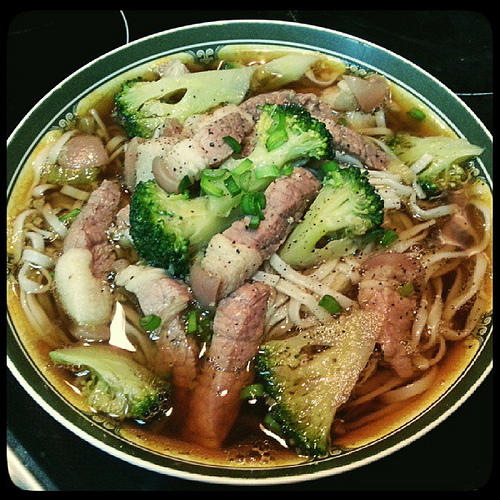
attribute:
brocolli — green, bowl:
[135, 170, 231, 254]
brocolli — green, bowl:
[107, 70, 272, 119]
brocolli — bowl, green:
[136, 172, 239, 262]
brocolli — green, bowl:
[49, 340, 170, 432]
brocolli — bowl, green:
[265, 149, 386, 242]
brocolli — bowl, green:
[248, 101, 386, 250]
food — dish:
[139, 150, 400, 369]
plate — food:
[393, 413, 416, 451]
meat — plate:
[196, 373, 239, 430]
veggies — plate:
[278, 323, 364, 411]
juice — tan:
[204, 435, 276, 456]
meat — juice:
[214, 312, 251, 358]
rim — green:
[434, 385, 463, 419]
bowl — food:
[22, 28, 484, 472]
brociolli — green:
[128, 178, 206, 261]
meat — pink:
[190, 299, 262, 426]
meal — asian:
[13, 49, 484, 449]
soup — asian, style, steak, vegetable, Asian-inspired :
[10, 50, 475, 450]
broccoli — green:
[51, 65, 476, 434]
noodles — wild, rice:
[11, 46, 462, 448]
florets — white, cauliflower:
[54, 245, 189, 333]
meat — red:
[184, 280, 269, 443]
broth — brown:
[240, 416, 285, 444]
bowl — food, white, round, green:
[4, 13, 473, 483]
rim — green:
[300, 370, 485, 479]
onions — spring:
[224, 177, 263, 228]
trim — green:
[17, 390, 471, 480]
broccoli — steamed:
[141, 104, 375, 294]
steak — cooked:
[186, 290, 280, 450]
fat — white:
[199, 230, 259, 293]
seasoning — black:
[102, 119, 371, 351]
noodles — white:
[8, 141, 477, 415]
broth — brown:
[121, 306, 488, 489]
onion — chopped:
[195, 152, 276, 226]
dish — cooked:
[6, 14, 496, 481]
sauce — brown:
[133, 379, 396, 479]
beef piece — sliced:
[179, 272, 279, 446]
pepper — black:
[106, 84, 413, 378]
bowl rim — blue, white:
[2, 25, 498, 488]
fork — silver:
[4, 425, 58, 499]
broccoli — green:
[112, 73, 377, 271]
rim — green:
[10, 14, 495, 486]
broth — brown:
[44, 58, 465, 459]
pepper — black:
[99, 98, 371, 323]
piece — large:
[53, 238, 120, 330]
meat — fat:
[201, 233, 268, 285]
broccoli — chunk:
[253, 307, 382, 459]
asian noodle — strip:
[402, 189, 452, 218]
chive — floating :
[402, 104, 423, 127]